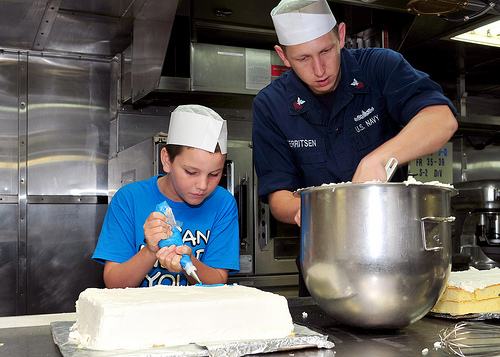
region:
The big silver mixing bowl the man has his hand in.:
[289, 195, 454, 332]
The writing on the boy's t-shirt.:
[140, 215, 213, 286]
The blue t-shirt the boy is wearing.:
[98, 174, 254, 279]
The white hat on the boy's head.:
[162, 94, 233, 159]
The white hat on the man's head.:
[266, 2, 341, 40]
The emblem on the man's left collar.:
[291, 92, 311, 108]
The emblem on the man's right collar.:
[339, 70, 360, 91]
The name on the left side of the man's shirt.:
[281, 137, 322, 148]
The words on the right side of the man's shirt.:
[338, 105, 384, 126]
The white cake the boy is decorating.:
[78, 278, 290, 353]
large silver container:
[293, 178, 459, 331]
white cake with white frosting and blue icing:
[51, 282, 331, 355]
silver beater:
[432, 316, 498, 355]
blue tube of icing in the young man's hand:
[149, 198, 206, 283]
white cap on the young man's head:
[166, 103, 231, 155]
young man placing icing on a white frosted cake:
[69, 103, 291, 355]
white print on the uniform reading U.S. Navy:
[352, 114, 392, 138]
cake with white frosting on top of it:
[430, 263, 498, 318]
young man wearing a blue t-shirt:
[91, 105, 266, 287]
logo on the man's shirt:
[285, 93, 306, 113]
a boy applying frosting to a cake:
[49, 100, 325, 355]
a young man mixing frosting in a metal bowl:
[252, 2, 459, 335]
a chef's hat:
[269, 2, 333, 45]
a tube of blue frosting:
[157, 205, 201, 282]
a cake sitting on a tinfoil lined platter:
[76, 288, 288, 342]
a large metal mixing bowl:
[297, 180, 454, 331]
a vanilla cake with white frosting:
[446, 268, 498, 313]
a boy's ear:
[160, 145, 172, 173]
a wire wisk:
[433, 322, 498, 353]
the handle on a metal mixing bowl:
[422, 215, 454, 225]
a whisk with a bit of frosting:
[421, 316, 496, 352]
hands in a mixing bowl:
[285, 151, 455, 311]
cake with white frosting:
[50, 281, 310, 351]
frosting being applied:
[142, 200, 222, 295]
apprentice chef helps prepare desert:
[106, 100, 266, 345]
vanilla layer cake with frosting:
[451, 247, 496, 312]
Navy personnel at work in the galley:
[247, 5, 453, 220]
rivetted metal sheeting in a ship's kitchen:
[0, 0, 90, 280]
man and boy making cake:
[90, 5, 435, 320]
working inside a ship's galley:
[23, 5, 488, 350]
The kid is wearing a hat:
[133, 90, 281, 230]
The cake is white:
[61, 255, 301, 344]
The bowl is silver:
[283, 170, 487, 349]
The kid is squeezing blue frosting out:
[140, 179, 271, 303]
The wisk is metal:
[426, 318, 498, 353]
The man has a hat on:
[248, 0, 381, 66]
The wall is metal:
[6, 40, 172, 233]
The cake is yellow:
[438, 269, 498, 324]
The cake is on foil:
[217, 330, 342, 355]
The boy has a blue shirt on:
[92, 160, 259, 307]